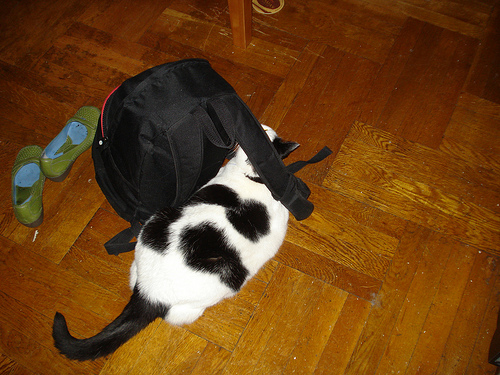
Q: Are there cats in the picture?
A: Yes, there is a cat.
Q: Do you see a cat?
A: Yes, there is a cat.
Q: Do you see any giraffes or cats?
A: Yes, there is a cat.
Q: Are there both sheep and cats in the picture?
A: No, there is a cat but no sheep.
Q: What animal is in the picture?
A: The animal is a cat.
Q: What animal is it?
A: The animal is a cat.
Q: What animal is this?
A: This is a cat.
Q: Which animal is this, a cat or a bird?
A: This is a cat.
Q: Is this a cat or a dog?
A: This is a cat.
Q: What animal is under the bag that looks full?
A: The cat is under the bag.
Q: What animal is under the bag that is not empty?
A: The animal is a cat.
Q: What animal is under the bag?
A: The animal is a cat.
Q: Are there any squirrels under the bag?
A: No, there is a cat under the bag.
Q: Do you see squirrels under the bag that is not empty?
A: No, there is a cat under the bag.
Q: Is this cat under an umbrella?
A: No, the cat is under the bag.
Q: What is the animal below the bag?
A: The animal is a cat.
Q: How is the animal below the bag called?
A: The animal is a cat.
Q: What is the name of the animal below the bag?
A: The animal is a cat.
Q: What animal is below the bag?
A: The animal is a cat.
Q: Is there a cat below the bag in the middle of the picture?
A: Yes, there is a cat below the bag.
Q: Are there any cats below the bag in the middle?
A: Yes, there is a cat below the bag.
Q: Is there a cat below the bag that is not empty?
A: Yes, there is a cat below the bag.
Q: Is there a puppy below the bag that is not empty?
A: No, there is a cat below the bag.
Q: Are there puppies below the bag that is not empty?
A: No, there is a cat below the bag.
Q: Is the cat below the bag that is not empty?
A: Yes, the cat is below the bag.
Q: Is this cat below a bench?
A: No, the cat is below the bag.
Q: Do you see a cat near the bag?
A: Yes, there is a cat near the bag.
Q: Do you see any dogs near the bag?
A: No, there is a cat near the bag.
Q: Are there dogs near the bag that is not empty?
A: No, there is a cat near the bag.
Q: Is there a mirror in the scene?
A: No, there are no mirrors.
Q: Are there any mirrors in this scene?
A: No, there are no mirrors.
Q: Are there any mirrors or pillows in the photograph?
A: No, there are no mirrors or pillows.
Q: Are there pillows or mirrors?
A: No, there are no mirrors or pillows.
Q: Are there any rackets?
A: No, there are no rackets.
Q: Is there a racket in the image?
A: No, there are no rackets.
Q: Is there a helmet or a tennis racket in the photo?
A: No, there are no rackets or helmets.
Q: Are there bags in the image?
A: Yes, there is a bag.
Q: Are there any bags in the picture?
A: Yes, there is a bag.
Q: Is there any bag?
A: Yes, there is a bag.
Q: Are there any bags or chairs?
A: Yes, there is a bag.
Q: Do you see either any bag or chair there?
A: Yes, there is a bag.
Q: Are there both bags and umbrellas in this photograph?
A: No, there is a bag but no umbrellas.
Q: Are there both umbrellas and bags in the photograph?
A: No, there is a bag but no umbrellas.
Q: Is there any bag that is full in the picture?
A: Yes, there is a full bag.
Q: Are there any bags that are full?
A: Yes, there is a bag that is full.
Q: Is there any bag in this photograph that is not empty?
A: Yes, there is an full bag.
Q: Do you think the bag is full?
A: Yes, the bag is full.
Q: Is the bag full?
A: Yes, the bag is full.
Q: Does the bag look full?
A: Yes, the bag is full.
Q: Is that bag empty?
A: No, the bag is full.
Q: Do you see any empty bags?
A: No, there is a bag but it is full.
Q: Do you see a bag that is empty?
A: No, there is a bag but it is full.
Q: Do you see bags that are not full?
A: No, there is a bag but it is full.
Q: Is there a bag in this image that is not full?
A: No, there is a bag but it is full.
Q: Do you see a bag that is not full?
A: No, there is a bag but it is full.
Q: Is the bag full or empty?
A: The bag is full.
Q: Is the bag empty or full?
A: The bag is full.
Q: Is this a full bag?
A: Yes, this is a full bag.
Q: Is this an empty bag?
A: No, this is a full bag.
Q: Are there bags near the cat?
A: Yes, there is a bag near the cat.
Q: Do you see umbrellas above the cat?
A: No, there is a bag above the cat.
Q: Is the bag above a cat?
A: Yes, the bag is above a cat.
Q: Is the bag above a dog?
A: No, the bag is above a cat.